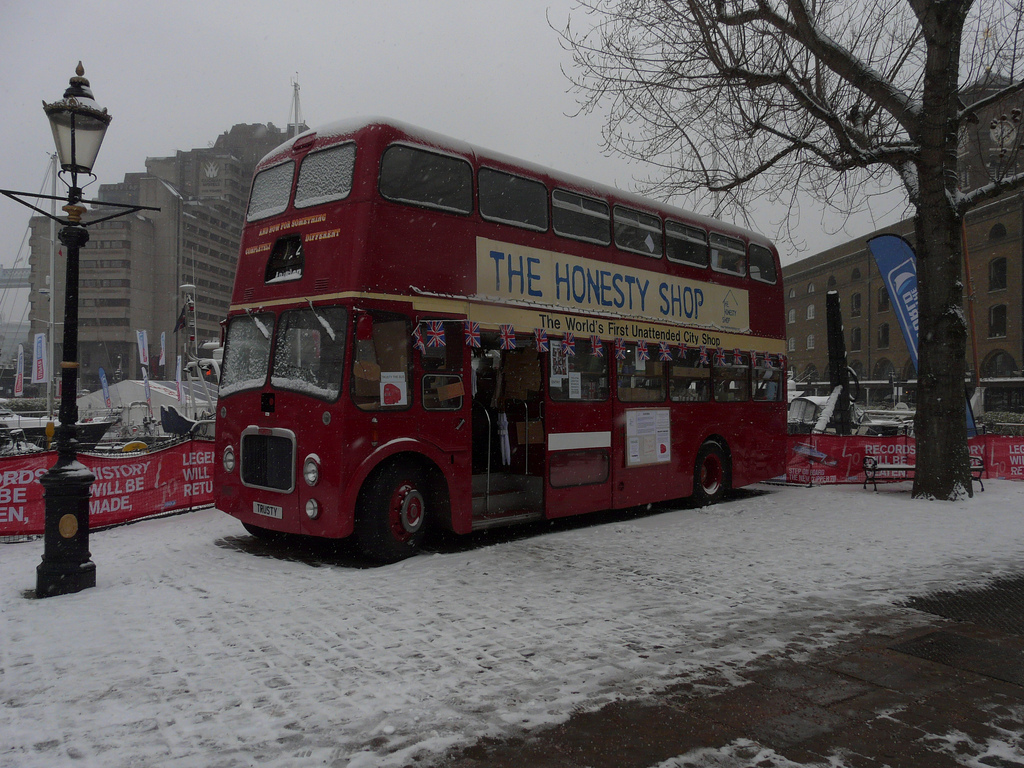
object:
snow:
[0, 437, 1022, 767]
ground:
[2, 434, 1023, 765]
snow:
[38, 59, 117, 117]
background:
[785, 0, 1023, 500]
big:
[205, 113, 789, 569]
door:
[466, 325, 548, 536]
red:
[2, 440, 212, 532]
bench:
[860, 453, 984, 492]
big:
[351, 460, 436, 568]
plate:
[250, 499, 285, 521]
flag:
[406, 318, 787, 377]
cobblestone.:
[417, 578, 1022, 767]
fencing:
[0, 436, 213, 541]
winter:
[0, 0, 1022, 767]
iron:
[0, 58, 164, 597]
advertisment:
[476, 236, 749, 334]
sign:
[862, 232, 979, 438]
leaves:
[544, 4, 1021, 503]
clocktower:
[936, 69, 1023, 199]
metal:
[859, 451, 988, 499]